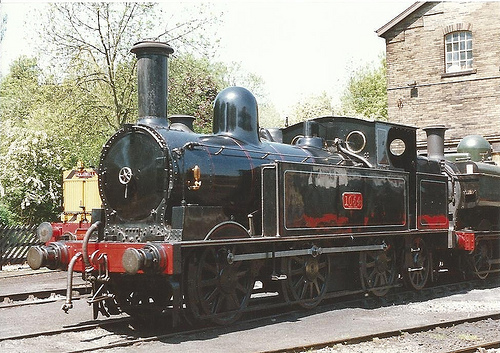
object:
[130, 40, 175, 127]
stack is on car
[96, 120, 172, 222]
front is round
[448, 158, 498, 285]
car is black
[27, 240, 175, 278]
bumper is red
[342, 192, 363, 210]
plate is red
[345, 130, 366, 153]
window is circular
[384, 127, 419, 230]
car has door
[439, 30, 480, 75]
building has window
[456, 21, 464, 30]
brick is brown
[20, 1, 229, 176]
tree is beside train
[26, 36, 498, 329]
train is in yard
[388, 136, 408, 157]
window is round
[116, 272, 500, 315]
tracks under train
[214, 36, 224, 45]
leaf is green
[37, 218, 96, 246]
front is red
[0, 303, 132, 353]
tracks under train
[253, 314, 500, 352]
tracks beside train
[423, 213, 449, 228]
paint is red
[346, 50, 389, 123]
tree is behind train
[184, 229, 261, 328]
train has wheel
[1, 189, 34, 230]
bush in background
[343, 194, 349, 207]
train has number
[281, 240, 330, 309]
train has wheel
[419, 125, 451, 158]
train has stack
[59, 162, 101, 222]
train is yellow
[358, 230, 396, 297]
train has wheel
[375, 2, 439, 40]
building has roof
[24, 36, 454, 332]
engine is old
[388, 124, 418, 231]
door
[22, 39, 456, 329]
engine car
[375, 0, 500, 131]
building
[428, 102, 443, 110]
bricks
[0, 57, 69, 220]
trees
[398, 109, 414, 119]
bricks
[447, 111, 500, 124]
stone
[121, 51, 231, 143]
trees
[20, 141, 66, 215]
leafy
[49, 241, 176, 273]
red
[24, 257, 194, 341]
front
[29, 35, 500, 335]
train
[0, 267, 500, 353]
tracks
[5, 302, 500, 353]
choo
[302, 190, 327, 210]
black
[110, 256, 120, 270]
redpaint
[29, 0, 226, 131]
one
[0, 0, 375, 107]
sky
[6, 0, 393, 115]
day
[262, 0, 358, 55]
blue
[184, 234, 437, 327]
four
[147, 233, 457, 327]
row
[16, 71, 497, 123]
background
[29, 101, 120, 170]
bushes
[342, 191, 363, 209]
number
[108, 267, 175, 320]
wheel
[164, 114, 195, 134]
stack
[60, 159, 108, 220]
building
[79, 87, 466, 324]
locomotive